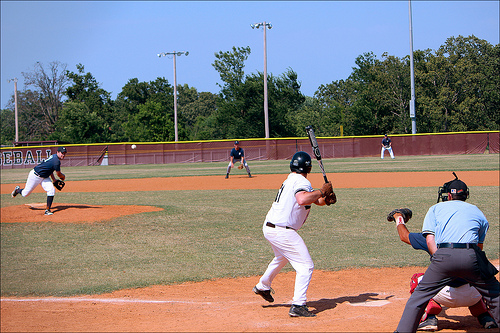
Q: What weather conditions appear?
A: It is clear.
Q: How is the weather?
A: It is clear.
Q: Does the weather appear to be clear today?
A: Yes, it is clear.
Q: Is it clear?
A: Yes, it is clear.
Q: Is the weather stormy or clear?
A: It is clear.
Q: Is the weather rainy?
A: No, it is clear.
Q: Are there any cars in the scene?
A: No, there are no cars.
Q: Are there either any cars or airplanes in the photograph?
A: No, there are no cars or airplanes.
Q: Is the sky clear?
A: Yes, the sky is clear.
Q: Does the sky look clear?
A: Yes, the sky is clear.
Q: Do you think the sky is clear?
A: Yes, the sky is clear.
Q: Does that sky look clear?
A: Yes, the sky is clear.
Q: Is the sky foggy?
A: No, the sky is clear.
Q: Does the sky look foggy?
A: No, the sky is clear.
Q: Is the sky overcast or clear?
A: The sky is clear.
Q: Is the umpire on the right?
A: Yes, the umpire is on the right of the image.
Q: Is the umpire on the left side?
A: No, the umpire is on the right of the image.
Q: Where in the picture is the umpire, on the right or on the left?
A: The umpire is on the right of the image.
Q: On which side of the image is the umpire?
A: The umpire is on the right of the image.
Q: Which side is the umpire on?
A: The umpire is on the right of the image.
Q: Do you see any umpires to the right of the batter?
A: Yes, there is an umpire to the right of the batter.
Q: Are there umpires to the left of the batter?
A: No, the umpire is to the right of the batter.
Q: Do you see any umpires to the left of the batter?
A: No, the umpire is to the right of the batter.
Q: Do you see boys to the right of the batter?
A: No, there is an umpire to the right of the batter.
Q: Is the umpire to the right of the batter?
A: Yes, the umpire is to the right of the batter.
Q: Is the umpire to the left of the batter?
A: No, the umpire is to the right of the batter.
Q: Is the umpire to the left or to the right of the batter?
A: The umpire is to the right of the batter.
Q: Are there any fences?
A: Yes, there is a fence.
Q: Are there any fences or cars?
A: Yes, there is a fence.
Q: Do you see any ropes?
A: No, there are no ropes.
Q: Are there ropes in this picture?
A: No, there are no ropes.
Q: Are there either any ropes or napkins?
A: No, there are no ropes or napkins.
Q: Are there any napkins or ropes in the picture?
A: No, there are no ropes or napkins.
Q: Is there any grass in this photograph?
A: Yes, there is grass.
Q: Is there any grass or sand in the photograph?
A: Yes, there is grass.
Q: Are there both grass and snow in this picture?
A: No, there is grass but no snow.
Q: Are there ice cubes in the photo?
A: No, there are no ice cubes.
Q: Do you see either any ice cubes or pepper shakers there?
A: No, there are no ice cubes or pepper shakers.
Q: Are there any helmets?
A: Yes, there is a helmet.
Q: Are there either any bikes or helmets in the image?
A: Yes, there is a helmet.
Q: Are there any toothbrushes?
A: No, there are no toothbrushes.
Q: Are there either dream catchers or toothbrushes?
A: No, there are no toothbrushes or dream catchers.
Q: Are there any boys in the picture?
A: No, there are no boys.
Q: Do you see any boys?
A: No, there are no boys.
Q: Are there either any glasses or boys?
A: No, there are no boys or glasses.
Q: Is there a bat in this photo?
A: Yes, there is a bat.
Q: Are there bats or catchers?
A: Yes, there is a bat.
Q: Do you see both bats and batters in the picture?
A: Yes, there are both a bat and a batter.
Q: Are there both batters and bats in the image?
A: Yes, there are both a bat and a batter.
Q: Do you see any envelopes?
A: No, there are no envelopes.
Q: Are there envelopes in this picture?
A: No, there are no envelopes.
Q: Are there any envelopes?
A: No, there are no envelopes.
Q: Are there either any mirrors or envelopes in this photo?
A: No, there are no envelopes or mirrors.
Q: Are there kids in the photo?
A: No, there are no kids.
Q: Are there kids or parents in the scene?
A: No, there are no kids or parents.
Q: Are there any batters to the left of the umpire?
A: Yes, there is a batter to the left of the umpire.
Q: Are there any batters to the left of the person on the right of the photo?
A: Yes, there is a batter to the left of the umpire.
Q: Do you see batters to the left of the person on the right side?
A: Yes, there is a batter to the left of the umpire.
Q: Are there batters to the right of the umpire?
A: No, the batter is to the left of the umpire.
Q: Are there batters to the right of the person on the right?
A: No, the batter is to the left of the umpire.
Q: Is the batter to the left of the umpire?
A: Yes, the batter is to the left of the umpire.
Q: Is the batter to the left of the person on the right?
A: Yes, the batter is to the left of the umpire.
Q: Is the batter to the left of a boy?
A: No, the batter is to the left of the umpire.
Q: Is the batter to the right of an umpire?
A: No, the batter is to the left of an umpire.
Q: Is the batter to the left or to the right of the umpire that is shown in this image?
A: The batter is to the left of the umpire.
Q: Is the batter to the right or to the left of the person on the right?
A: The batter is to the left of the umpire.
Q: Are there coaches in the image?
A: No, there are no coaches.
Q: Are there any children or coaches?
A: No, there are no coaches or children.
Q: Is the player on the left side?
A: Yes, the player is on the left of the image.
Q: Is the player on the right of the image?
A: No, the player is on the left of the image.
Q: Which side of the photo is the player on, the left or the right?
A: The player is on the left of the image.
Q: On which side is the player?
A: The player is on the left of the image.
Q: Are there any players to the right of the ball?
A: No, the player is to the left of the ball.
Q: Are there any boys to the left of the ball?
A: No, there is a player to the left of the ball.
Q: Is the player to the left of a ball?
A: Yes, the player is to the left of a ball.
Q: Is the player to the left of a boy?
A: No, the player is to the left of a ball.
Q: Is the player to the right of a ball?
A: No, the player is to the left of a ball.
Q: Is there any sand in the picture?
A: Yes, there is sand.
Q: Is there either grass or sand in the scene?
A: Yes, there is sand.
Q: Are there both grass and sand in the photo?
A: Yes, there are both sand and grass.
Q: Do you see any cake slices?
A: No, there are no cake slices.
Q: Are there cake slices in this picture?
A: No, there are no cake slices.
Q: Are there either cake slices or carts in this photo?
A: No, there are no cake slices or carts.